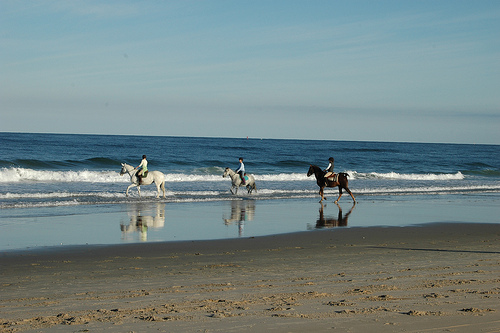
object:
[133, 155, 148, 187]
person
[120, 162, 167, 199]
horse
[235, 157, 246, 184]
person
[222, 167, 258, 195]
horse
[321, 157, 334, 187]
person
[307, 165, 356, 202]
horse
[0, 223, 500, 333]
beach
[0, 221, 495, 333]
sand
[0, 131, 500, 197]
ocean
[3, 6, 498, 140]
sky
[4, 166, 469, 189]
waves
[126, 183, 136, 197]
legs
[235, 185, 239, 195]
legs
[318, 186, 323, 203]
legs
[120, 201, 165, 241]
reflection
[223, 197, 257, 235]
reflection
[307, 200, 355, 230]
reflection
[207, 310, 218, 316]
footprints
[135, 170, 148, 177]
saddle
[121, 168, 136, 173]
reins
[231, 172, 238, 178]
reins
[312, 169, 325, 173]
reins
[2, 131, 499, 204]
water